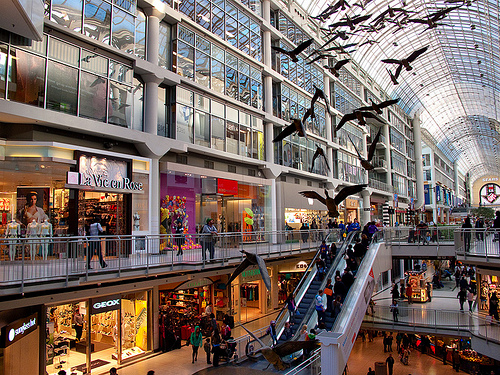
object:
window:
[239, 182, 269, 244]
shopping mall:
[2, 2, 497, 373]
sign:
[74, 151, 131, 193]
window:
[2, 161, 70, 260]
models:
[374, 0, 395, 37]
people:
[309, 290, 332, 326]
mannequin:
[4, 214, 21, 264]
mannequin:
[22, 215, 38, 265]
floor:
[46, 248, 81, 274]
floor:
[404, 236, 437, 247]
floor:
[437, 294, 458, 307]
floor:
[174, 345, 190, 361]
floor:
[356, 340, 377, 360]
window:
[158, 175, 268, 251]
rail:
[5, 229, 61, 252]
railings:
[370, 301, 392, 313]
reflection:
[213, 39, 263, 109]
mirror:
[91, 312, 123, 362]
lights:
[121, 298, 138, 317]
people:
[323, 278, 335, 311]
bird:
[353, 93, 398, 119]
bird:
[381, 43, 429, 75]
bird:
[408, 6, 461, 33]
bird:
[271, 38, 318, 62]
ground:
[439, 211, 453, 218]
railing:
[96, 227, 122, 249]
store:
[43, 287, 152, 373]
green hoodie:
[188, 325, 203, 350]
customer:
[185, 323, 205, 365]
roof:
[449, 0, 497, 63]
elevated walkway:
[0, 257, 46, 281]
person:
[82, 215, 108, 270]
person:
[298, 223, 311, 243]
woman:
[205, 301, 214, 318]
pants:
[190, 345, 200, 361]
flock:
[306, 229, 355, 342]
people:
[282, 290, 299, 325]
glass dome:
[460, 127, 499, 182]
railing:
[404, 299, 433, 313]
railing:
[156, 231, 217, 246]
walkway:
[257, 219, 330, 249]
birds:
[296, 184, 373, 223]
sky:
[180, 20, 212, 53]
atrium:
[394, 139, 497, 189]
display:
[159, 192, 197, 251]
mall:
[1, 1, 498, 373]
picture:
[2, 4, 498, 364]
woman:
[196, 217, 218, 267]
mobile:
[313, 3, 366, 46]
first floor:
[164, 352, 182, 373]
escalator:
[228, 223, 393, 370]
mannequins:
[35, 215, 51, 261]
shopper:
[453, 284, 469, 316]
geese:
[298, 82, 340, 109]